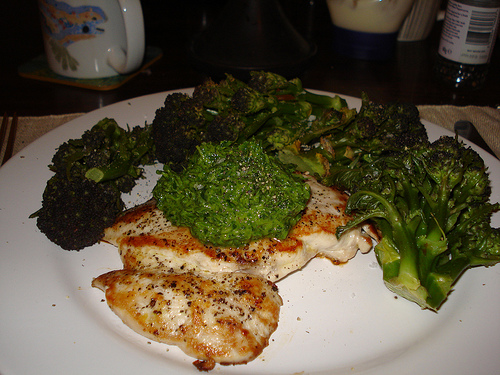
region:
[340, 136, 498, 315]
a piece of broccoli on a plate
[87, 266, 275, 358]
piece of seasoned chicken on a plate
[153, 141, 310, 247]
a green sauce piled atop a piece of chicken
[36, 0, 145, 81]
a white coffee mug with a frog on it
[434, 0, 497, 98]
a pepper grinder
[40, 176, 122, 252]
a piece of broccoli on a plate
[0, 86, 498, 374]
a round white dinner plate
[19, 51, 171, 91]
a cup coaster under a mug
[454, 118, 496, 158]
a butter knife beside a plate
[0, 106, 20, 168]
a fork beside a plate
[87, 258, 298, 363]
piece of meat with seasoning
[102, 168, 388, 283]
piece of meat with seasoning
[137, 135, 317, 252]
green leafy vegetable on a plate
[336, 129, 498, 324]
green leafy vegetable on a plate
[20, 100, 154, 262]
green leafy vegetable on a plate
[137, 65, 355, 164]
green leafy vegetable on a plate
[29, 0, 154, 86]
white coffee cup with design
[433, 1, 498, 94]
plastic bottle with label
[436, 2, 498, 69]
white label on a water bottle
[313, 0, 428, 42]
coffee cup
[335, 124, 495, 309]
a piece of broccoli.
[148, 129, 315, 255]
a serving of spinach.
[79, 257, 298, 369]
a piece of broiled chicken.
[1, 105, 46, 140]
a white and brown table cloth.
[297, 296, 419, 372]
a white saucer.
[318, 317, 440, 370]
a big round dish.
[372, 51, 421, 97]
a dark brown table.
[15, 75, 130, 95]
a yellow coaster.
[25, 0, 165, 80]
a flowered cup.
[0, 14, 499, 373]
a plate of food with grilled chicken and broccoli.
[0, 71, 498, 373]
A plate of food.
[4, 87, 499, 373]
A round with plate.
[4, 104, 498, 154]
A beige placemat.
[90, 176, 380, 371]
Cooked golden brown chicken.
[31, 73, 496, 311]
Cooked broccoli.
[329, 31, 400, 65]
A blue lid.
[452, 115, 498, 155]
A silver knife.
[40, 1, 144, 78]
A white coffee mug with a design.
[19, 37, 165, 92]
A drink coaster.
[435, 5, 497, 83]
A clear bottle with a white label.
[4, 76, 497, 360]
A plain white plate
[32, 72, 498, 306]
broccoli on the plate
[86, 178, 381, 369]
meat on the plate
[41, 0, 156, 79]
A white cup on the counter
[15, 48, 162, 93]
Coaster to put cups on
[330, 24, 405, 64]
top to a topping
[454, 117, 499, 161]
silverware on the side of the plate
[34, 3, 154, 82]
A frog design is on the cup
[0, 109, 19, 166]
chopsticks are on the side of the plate